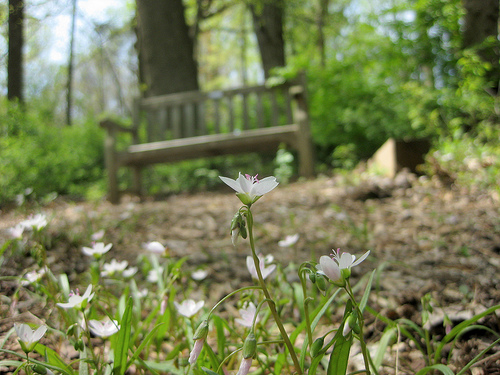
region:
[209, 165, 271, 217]
the flowers are white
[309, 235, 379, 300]
the flowers are white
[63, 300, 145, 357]
the flowers are white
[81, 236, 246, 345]
the flowers are white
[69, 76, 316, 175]
the bench is empty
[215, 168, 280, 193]
a white flower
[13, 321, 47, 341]
the small flower is white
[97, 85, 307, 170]
a bench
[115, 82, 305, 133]
the bench is brown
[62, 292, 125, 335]
small flowers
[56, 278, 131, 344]
the small flowers are in the grass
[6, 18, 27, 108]
a tree trunk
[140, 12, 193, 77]
a tree trunk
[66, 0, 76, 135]
a long tree trunk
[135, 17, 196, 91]
the tree is brown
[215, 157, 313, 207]
Flower is white color.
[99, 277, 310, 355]
Leaves are green color.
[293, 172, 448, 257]
Ground is brown color.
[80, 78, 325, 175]
Bench is brown color.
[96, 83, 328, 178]
Bench is made of wood.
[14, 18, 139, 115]
sky is blue color.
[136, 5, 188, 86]
woods are brown color.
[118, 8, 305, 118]
Trees are behind the bench.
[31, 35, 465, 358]
Day time picture.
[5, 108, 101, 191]
Bushes are green color.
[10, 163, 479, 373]
white flowers growing in grass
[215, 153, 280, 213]
flower has pink center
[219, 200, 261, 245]
flower has an additional but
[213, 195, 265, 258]
additional bud has not opened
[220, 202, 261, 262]
additional bud has white tip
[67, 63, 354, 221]
bench sitting in background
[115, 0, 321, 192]
two trees behind bench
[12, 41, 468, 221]
green bushed behind bench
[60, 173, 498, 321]
ground has brown grass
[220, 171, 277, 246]
Small white flower with a pink center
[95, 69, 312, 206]
Outdoor bench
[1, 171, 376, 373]
Cluster of flowers with pink centers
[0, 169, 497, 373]
Trail with debris scattered about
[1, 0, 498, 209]
Green, forested background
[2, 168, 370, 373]
Group of small, delicate white flowers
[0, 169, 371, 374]
Tiny white flowers with pink stamen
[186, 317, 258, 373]
White flower blossoms that are closed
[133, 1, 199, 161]
Large tree trunk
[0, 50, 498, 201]
Overgrowth of plants and weeds